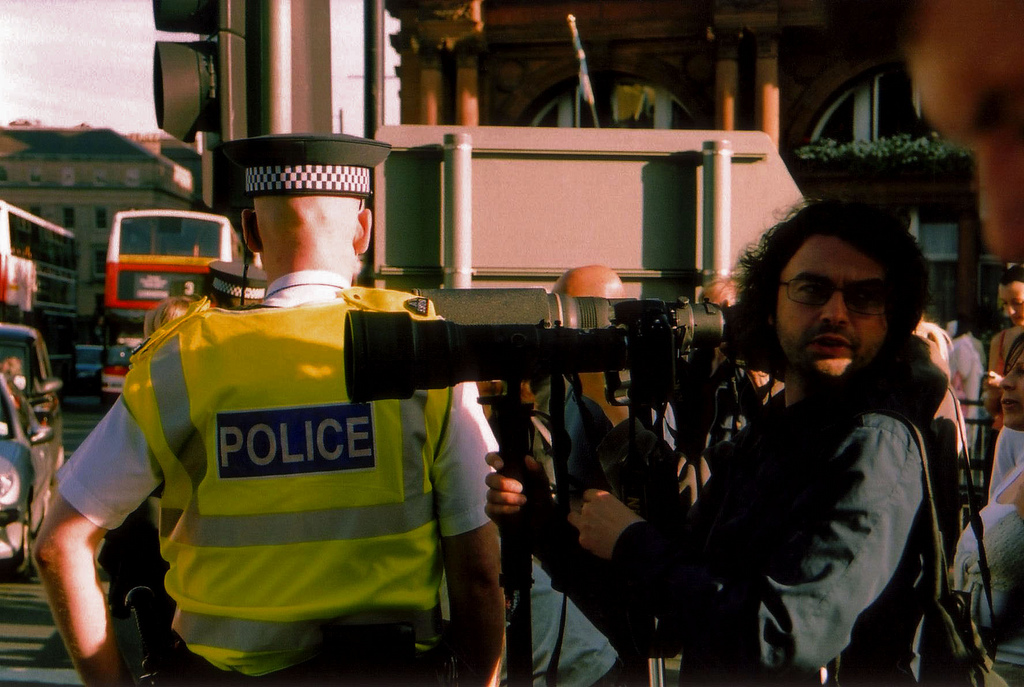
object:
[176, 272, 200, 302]
number 3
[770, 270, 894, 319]
eye glasses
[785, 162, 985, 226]
pot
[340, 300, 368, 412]
lens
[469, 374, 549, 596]
monopod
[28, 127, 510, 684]
man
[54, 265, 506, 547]
white shirt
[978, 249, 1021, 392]
person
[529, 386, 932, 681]
dark shirt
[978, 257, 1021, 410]
person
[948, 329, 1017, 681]
person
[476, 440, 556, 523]
hand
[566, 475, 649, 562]
hand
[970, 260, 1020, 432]
person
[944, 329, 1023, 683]
person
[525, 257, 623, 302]
bald head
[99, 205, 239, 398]
bus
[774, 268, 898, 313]
spectacles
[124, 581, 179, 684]
baton's handle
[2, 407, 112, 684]
road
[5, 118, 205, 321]
building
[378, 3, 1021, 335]
building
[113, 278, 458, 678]
police vest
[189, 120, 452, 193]
hat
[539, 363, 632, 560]
pole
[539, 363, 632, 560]
camera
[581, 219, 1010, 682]
man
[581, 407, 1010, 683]
top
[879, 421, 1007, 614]
bag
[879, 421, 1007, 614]
shoulder